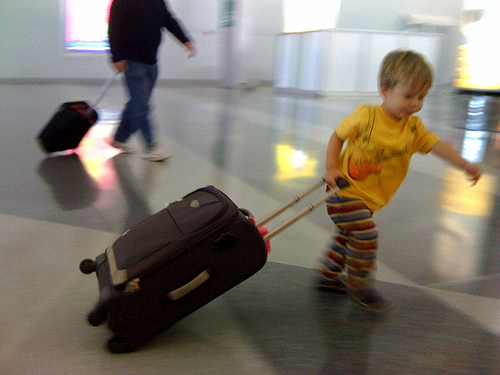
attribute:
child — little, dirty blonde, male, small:
[309, 44, 485, 308]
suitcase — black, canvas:
[68, 171, 350, 358]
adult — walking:
[101, 2, 201, 166]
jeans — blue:
[110, 62, 164, 149]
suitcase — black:
[34, 65, 127, 157]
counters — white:
[267, 26, 445, 109]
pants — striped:
[317, 184, 384, 295]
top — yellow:
[323, 98, 440, 209]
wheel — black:
[102, 336, 125, 355]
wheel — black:
[86, 312, 111, 330]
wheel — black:
[77, 257, 100, 275]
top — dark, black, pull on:
[105, 1, 194, 67]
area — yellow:
[272, 143, 319, 184]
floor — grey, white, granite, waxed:
[1, 80, 500, 374]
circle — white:
[289, 150, 308, 170]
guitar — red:
[347, 147, 410, 183]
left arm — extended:
[418, 123, 490, 186]